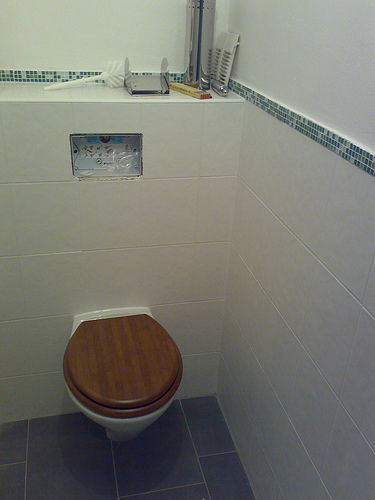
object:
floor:
[3, 390, 259, 500]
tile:
[0, 395, 257, 498]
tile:
[0, 87, 245, 310]